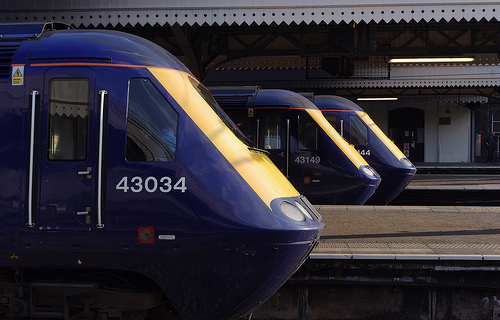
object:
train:
[190, 87, 421, 209]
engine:
[0, 264, 168, 317]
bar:
[97, 90, 105, 225]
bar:
[28, 91, 35, 225]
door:
[38, 68, 93, 229]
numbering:
[116, 176, 187, 193]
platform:
[333, 205, 495, 254]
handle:
[93, 88, 106, 229]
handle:
[25, 90, 37, 225]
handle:
[287, 119, 290, 178]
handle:
[256, 119, 259, 150]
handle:
[340, 120, 343, 137]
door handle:
[77, 167, 92, 179]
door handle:
[77, 207, 92, 225]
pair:
[69, 162, 94, 222]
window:
[48, 79, 90, 161]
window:
[261, 112, 282, 149]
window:
[350, 116, 369, 145]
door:
[257, 115, 288, 174]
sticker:
[142, 68, 304, 211]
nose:
[264, 195, 327, 250]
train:
[209, 73, 376, 225]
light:
[279, 200, 315, 222]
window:
[126, 74, 179, 162]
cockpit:
[20, 36, 328, 319]